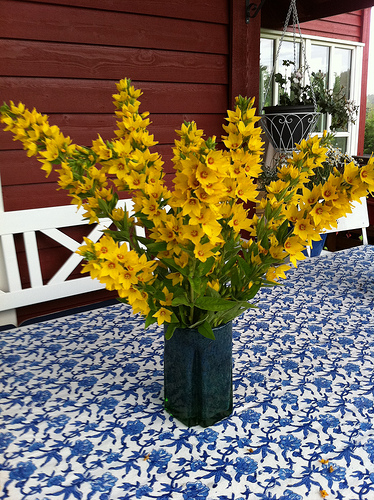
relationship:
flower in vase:
[84, 140, 292, 276] [171, 338, 250, 404]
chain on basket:
[282, 17, 316, 71] [270, 99, 327, 131]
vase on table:
[171, 338, 250, 404] [294, 303, 345, 345]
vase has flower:
[171, 338, 250, 404] [84, 140, 292, 276]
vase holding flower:
[171, 338, 250, 404] [84, 140, 292, 276]